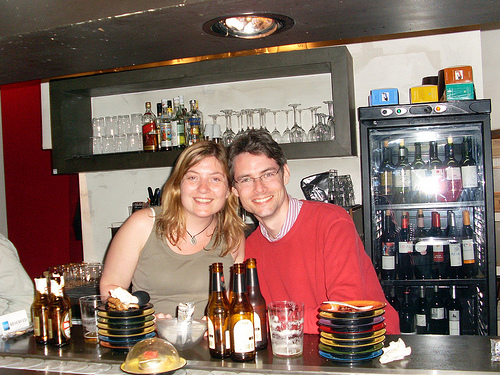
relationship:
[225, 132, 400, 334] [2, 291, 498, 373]
man standing behind bar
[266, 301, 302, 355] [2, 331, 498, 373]
glass on counter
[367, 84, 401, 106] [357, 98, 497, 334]
box on cooler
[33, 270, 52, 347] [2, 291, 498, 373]
bottle on bar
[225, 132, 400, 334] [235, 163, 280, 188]
man has glasses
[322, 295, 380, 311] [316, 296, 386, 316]
spoon on plate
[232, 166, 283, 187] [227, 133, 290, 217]
glasses on man's face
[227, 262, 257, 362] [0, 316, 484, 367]
bottle standing on top of counter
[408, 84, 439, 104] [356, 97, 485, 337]
box sitting on top of cooler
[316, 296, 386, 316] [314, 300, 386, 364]
plate sitting in stack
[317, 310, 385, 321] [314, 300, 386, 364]
plate sitting in stack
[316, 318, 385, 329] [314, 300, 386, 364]
plate sitting in stack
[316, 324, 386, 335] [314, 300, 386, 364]
plate sitting in stack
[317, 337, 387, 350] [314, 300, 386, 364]
plate sitting in stack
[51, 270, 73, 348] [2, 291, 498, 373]
bottle standing on top of bar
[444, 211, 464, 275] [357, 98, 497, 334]
bottle standing inside cooler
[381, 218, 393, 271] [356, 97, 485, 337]
bottle standing inside cooler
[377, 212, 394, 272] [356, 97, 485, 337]
bottle standing inside cooler